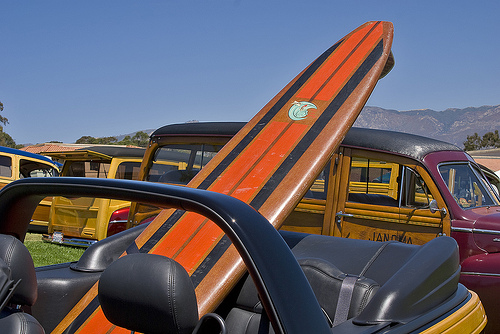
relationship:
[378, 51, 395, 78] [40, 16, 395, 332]
fin on surfboard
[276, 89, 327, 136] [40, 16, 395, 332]
logo on surfboard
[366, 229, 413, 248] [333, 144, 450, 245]
writing on door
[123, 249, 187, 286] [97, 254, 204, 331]
headrest on seat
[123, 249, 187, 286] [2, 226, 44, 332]
headrest on seat